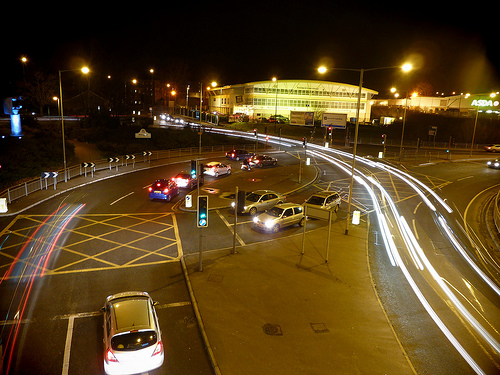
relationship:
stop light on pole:
[184, 191, 220, 228] [188, 236, 220, 268]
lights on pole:
[317, 57, 419, 81] [317, 50, 411, 242]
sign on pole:
[300, 199, 336, 223] [321, 208, 336, 267]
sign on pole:
[40, 170, 60, 182] [44, 170, 59, 192]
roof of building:
[234, 76, 366, 91] [182, 60, 392, 133]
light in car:
[154, 180, 161, 188] [146, 176, 178, 201]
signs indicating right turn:
[22, 142, 177, 187] [161, 92, 445, 372]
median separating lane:
[181, 207, 419, 374] [365, 163, 497, 372]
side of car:
[147, 296, 169, 361] [98, 289, 165, 374]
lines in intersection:
[2, 140, 457, 288] [90, 120, 443, 257]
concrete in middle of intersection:
[183, 271, 400, 363] [65, 141, 480, 370]